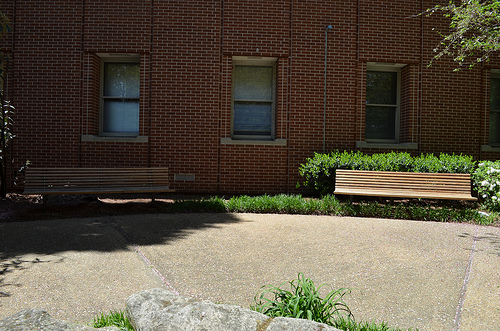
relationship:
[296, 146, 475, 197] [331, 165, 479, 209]
bushes behind bench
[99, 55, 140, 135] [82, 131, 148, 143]
window has window sill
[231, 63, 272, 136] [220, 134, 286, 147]
window has window sill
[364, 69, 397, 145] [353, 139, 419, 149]
window has window sill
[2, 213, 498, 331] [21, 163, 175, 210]
walkway in front of bench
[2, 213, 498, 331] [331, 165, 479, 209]
walkway in front of bench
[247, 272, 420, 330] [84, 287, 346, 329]
grass next to rock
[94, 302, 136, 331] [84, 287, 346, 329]
grass between rock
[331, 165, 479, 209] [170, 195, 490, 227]
bench behind grass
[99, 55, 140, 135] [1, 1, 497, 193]
window part of building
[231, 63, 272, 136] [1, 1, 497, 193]
window part of building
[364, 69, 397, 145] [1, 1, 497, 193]
window part of building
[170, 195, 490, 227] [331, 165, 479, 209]
grass underneath bench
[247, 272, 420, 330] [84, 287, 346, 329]
grass surrounding rock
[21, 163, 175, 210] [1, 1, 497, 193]
bench in front of building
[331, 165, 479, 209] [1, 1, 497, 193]
bench in front of building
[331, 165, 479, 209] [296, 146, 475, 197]
bench in front of bushes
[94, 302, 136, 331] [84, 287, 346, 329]
grass in between rock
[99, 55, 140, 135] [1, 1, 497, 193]
window on side of building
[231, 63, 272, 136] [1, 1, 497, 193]
window on side of building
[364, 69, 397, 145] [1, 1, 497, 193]
window on side of building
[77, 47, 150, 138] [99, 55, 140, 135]
brick around window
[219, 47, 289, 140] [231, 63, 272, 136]
brick around window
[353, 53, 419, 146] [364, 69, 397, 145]
brick around window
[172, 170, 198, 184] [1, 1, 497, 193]
vent on side of building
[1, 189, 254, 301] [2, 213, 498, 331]
shadow cast on walkway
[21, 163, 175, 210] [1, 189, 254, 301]
bench hidden in shadow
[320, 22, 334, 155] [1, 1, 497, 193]
conduit attached to building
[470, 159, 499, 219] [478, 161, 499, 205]
shrub with flowers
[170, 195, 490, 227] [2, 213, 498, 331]
grass beside walkway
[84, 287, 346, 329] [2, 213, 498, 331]
rock next to walkway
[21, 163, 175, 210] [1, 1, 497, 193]
bench outside of building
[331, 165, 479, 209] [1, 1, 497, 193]
bench outside of building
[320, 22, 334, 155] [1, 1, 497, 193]
conduit on side of building